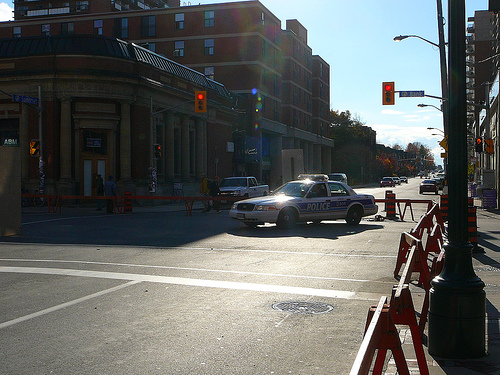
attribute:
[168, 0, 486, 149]
sky — open, big, clear, white, blue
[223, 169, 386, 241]
car — police, blue, white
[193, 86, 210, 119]
light — yellow, red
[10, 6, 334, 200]
building — orange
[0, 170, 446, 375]
road — grey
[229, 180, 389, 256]
car — police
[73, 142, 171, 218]
doors — wood and glass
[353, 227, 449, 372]
barriers — emergency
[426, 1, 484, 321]
pole — tall, metal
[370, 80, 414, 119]
light — red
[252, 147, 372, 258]
car — police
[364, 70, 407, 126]
light — red, stop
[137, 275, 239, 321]
lines — white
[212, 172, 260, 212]
truck — white